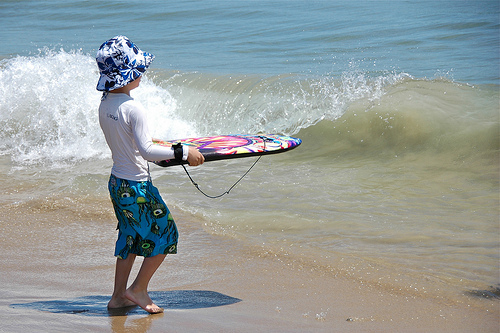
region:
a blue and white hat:
[90, 25, 149, 82]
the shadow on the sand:
[172, 275, 217, 312]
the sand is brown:
[234, 270, 371, 323]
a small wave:
[322, 71, 445, 155]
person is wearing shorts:
[111, 188, 178, 251]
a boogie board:
[201, 125, 289, 155]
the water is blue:
[269, 8, 402, 64]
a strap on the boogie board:
[168, 142, 188, 164]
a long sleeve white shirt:
[103, 107, 160, 179]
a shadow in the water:
[450, 280, 494, 302]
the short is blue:
[91, 168, 209, 278]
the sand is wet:
[193, 265, 229, 312]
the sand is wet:
[196, 258, 272, 326]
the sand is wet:
[49, 269, 151, 331]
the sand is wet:
[135, 267, 231, 326]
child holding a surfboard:
[148, 115, 303, 181]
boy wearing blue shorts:
[86, 173, 199, 278]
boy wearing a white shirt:
[86, 83, 186, 202]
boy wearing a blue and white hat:
[80, 33, 153, 96]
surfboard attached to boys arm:
[153, 134, 245, 205]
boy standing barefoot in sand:
[93, 265, 168, 325]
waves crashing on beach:
[196, 79, 341, 166]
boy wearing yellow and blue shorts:
[96, 173, 191, 290]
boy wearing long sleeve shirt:
[91, 110, 196, 205]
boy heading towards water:
[78, 42, 218, 304]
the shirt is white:
[80, 73, 200, 208]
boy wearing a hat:
[76, 30, 169, 152]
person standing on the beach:
[94, 49, 295, 313]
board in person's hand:
[145, 136, 300, 158]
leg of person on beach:
[125, 249, 170, 316]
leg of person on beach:
[109, 253, 137, 310]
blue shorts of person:
[107, 178, 178, 259]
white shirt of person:
[101, 96, 194, 176]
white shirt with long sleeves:
[102, 94, 190, 180]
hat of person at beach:
[95, 33, 157, 90]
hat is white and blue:
[92, 38, 157, 90]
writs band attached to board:
[172, 142, 182, 160]